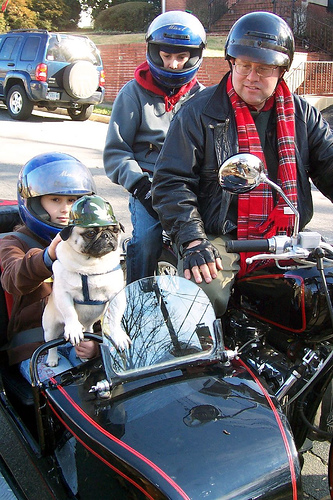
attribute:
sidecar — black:
[1, 192, 301, 499]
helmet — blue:
[11, 147, 104, 237]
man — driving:
[150, 14, 332, 284]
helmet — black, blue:
[216, 16, 315, 102]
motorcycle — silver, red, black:
[134, 219, 333, 479]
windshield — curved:
[95, 275, 232, 383]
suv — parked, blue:
[1, 30, 108, 124]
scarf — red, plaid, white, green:
[219, 73, 310, 270]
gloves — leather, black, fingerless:
[178, 243, 230, 287]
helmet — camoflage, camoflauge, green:
[63, 196, 127, 239]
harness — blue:
[59, 257, 126, 312]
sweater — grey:
[108, 83, 209, 199]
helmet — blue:
[142, 8, 206, 86]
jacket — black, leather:
[160, 78, 332, 251]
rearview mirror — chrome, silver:
[217, 154, 269, 194]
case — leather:
[65, 61, 103, 104]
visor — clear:
[28, 156, 99, 205]